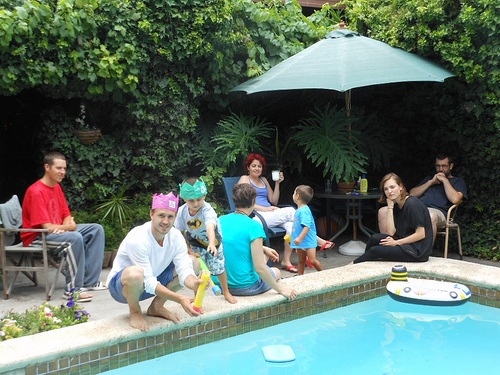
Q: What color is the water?
A: Blue.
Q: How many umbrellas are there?
A: One.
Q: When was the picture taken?
A: Daytime.